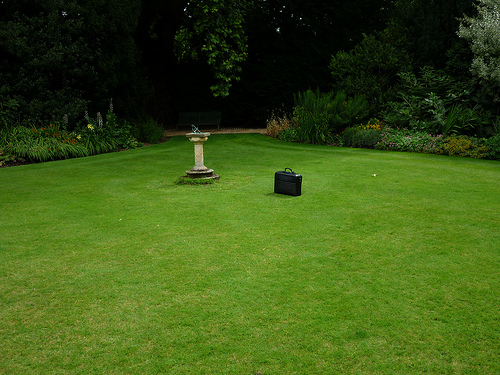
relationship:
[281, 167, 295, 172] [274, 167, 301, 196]
handle on suitcase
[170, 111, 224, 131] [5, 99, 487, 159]
bench on background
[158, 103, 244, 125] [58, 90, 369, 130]
bench on shade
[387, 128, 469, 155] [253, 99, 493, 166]
leaves in bush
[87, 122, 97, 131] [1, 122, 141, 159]
flower in bush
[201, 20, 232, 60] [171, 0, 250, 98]
leaves on tree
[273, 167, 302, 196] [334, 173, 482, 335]
briefcase in grass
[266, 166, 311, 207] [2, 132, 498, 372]
briefcase in grass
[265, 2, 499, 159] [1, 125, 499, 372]
plants on ground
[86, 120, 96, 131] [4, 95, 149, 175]
flower on plant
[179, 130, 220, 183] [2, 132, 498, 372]
decoration on grass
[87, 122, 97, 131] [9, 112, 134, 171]
flower on plants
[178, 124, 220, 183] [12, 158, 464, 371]
decoration on lawn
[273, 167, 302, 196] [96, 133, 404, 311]
briefcase in back yard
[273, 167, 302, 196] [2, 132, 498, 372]
briefcase on grass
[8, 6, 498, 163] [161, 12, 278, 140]
leaves hanging from tree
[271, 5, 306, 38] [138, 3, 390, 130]
sky showing through trees